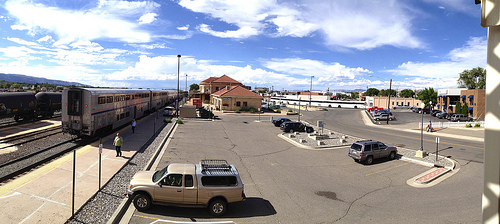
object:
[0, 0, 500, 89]
sky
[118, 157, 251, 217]
truck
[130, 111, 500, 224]
street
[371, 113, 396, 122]
vehicles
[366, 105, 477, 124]
parking lot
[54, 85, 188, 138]
train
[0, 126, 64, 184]
train tracks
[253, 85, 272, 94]
building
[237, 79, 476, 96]
distance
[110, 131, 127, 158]
people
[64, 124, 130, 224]
sidewalk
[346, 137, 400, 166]
truck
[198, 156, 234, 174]
racks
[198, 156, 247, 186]
add on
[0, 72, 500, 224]
train station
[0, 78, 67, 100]
background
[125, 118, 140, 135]
people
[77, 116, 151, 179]
platform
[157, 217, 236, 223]
line